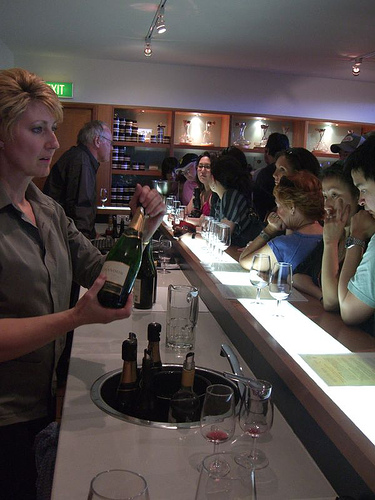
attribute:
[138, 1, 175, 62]
lighting — track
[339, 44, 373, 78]
lighting — track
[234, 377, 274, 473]
wine glass — clear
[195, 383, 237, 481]
wine glass — clear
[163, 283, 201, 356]
beer mug — glass, clear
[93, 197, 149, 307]
bottle — green, champagne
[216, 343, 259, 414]
faucet — silver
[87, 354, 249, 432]
sink — round, silver, steel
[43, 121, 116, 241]
man — standing, elderly, taking orders, answering questions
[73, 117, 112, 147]
hair — gray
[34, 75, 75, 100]
sign — green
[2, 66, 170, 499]
woman — looking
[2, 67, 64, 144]
hair — blonde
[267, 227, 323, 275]
shirt — blue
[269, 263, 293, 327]
wine glass — empty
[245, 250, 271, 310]
wine glass — empty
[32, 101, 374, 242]
shelves — wooden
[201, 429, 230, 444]
wine — leftover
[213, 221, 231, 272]
glass — empty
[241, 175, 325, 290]
woman — middle age